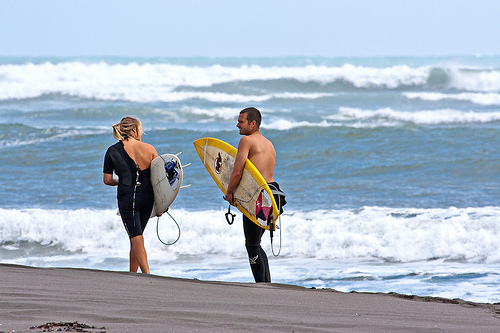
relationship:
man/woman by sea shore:
[95, 101, 289, 290] [8, 250, 426, 328]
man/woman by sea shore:
[95, 101, 289, 290] [1, 227, 451, 320]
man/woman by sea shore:
[95, 101, 289, 290] [3, 230, 398, 323]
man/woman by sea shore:
[95, 101, 289, 290] [1, 230, 443, 330]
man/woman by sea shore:
[95, 101, 289, 290] [0, 238, 460, 330]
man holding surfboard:
[193, 106, 287, 283] [185, 133, 288, 236]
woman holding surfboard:
[102, 115, 193, 274] [144, 148, 194, 223]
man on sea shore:
[193, 106, 287, 283] [67, 270, 320, 331]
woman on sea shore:
[102, 115, 193, 274] [67, 270, 320, 331]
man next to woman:
[193, 106, 287, 283] [102, 115, 193, 274]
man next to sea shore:
[193, 106, 287, 283] [96, 285, 284, 331]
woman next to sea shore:
[102, 115, 193, 274] [96, 285, 284, 331]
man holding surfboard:
[193, 106, 287, 283] [140, 149, 187, 223]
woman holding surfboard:
[102, 115, 193, 274] [185, 130, 282, 239]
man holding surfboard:
[193, 106, 287, 283] [191, 134, 287, 232]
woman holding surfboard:
[102, 113, 181, 277] [142, 148, 195, 219]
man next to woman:
[193, 106, 287, 283] [102, 113, 181, 277]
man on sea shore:
[193, 106, 287, 283] [96, 282, 276, 326]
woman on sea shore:
[102, 113, 181, 277] [96, 282, 276, 326]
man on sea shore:
[196, 103, 293, 291] [128, 285, 308, 329]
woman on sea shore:
[102, 115, 193, 274] [128, 285, 308, 329]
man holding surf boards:
[196, 103, 293, 291] [190, 133, 284, 234]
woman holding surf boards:
[102, 115, 193, 274] [143, 150, 192, 220]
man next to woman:
[196, 103, 293, 291] [102, 115, 193, 274]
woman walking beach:
[102, 115, 193, 274] [6, 261, 485, 331]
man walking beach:
[193, 106, 287, 283] [6, 261, 485, 331]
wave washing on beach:
[309, 212, 461, 264] [8, 265, 302, 331]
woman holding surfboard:
[102, 115, 193, 274] [146, 151, 189, 223]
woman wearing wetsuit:
[102, 115, 193, 274] [104, 150, 154, 236]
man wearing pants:
[193, 106, 287, 283] [241, 180, 293, 281]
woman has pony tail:
[102, 115, 193, 274] [112, 120, 129, 140]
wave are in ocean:
[309, 217, 475, 256] [7, 58, 496, 254]